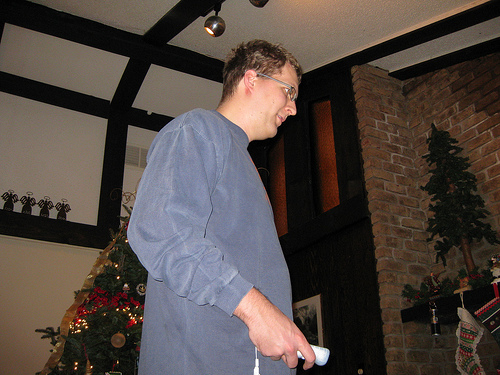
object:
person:
[126, 38, 316, 375]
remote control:
[295, 345, 331, 366]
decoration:
[55, 198, 72, 221]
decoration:
[37, 196, 55, 218]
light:
[202, 13, 226, 38]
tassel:
[250, 346, 262, 374]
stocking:
[453, 306, 487, 374]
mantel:
[400, 280, 499, 323]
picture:
[290, 290, 325, 348]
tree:
[36, 203, 149, 374]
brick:
[399, 217, 425, 230]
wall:
[352, 64, 495, 375]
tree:
[420, 120, 498, 280]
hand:
[245, 302, 315, 369]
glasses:
[243, 69, 297, 101]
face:
[248, 62, 299, 138]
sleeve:
[124, 112, 257, 316]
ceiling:
[0, 0, 498, 76]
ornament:
[111, 333, 126, 348]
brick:
[360, 125, 389, 141]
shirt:
[126, 107, 300, 374]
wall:
[251, 60, 388, 374]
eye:
[281, 86, 293, 94]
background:
[0, 0, 500, 373]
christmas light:
[115, 308, 120, 312]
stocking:
[473, 298, 497, 345]